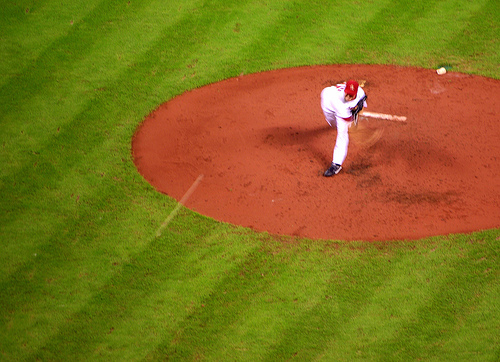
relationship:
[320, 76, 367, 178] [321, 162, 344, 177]
person has shoe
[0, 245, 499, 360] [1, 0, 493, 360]
grass on ground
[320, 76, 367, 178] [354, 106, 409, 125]
person has bat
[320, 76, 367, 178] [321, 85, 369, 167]
person wearing clothing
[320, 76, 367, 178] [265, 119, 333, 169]
person has shadow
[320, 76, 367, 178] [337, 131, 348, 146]
person has knee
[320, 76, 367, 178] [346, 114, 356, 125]
person has elbow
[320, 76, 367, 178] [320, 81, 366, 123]
person wearing shirt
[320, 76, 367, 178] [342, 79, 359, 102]
person has head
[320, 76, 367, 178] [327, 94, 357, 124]
person has arm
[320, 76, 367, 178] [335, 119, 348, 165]
person has leg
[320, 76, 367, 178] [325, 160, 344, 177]
person has foot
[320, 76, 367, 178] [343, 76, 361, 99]
person has hat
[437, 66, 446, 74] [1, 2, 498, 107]
ball in air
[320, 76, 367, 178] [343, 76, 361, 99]
person wearing hat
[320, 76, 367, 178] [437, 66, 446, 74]
person throwing ball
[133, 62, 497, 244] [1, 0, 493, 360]
mound on field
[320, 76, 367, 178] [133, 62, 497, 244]
person on mound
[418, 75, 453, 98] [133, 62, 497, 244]
markings on mound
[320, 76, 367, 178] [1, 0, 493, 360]
person bending over ground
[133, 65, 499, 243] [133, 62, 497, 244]
dirt on mound